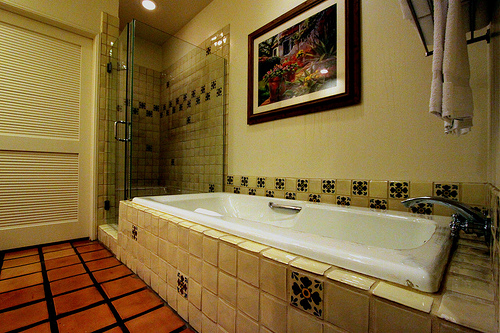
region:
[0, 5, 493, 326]
A bathroom in a house.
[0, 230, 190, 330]
Red tile on a floor.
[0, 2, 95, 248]
A white wooden door.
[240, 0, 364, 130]
Picture hanging on a wall.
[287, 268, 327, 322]
Decorative piece of tile.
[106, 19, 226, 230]
Glass shower door.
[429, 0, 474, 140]
Towels on a towel rack.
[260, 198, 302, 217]
Silver handle in a bathtub.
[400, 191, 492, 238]
Silver tub spout.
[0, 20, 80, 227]
Wooden slats on a door.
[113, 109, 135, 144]
Entrance to the glass door.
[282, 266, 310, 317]
Entrance to the glass door.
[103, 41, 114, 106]
Entrance to the glass door.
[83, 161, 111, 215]
Entrance to the glass door.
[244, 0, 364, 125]
a framed painting on wall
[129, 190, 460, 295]
a white porcelain bath tub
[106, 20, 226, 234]
a glass shower stall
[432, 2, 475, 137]
hanging tan towel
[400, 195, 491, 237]
chrome bath tub faucet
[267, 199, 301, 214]
chrome grab bar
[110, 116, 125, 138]
chrome shower door handle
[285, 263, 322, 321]
a decorative bathroom tile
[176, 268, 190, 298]
a decorative bathroom tile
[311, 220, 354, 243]
the sink is white in color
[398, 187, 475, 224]
this is a tap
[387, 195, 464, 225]
the tap is metallic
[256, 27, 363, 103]
this is a picture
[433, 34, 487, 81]
the towel is white in color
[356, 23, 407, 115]
this is the wall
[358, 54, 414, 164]
the wall is cream in color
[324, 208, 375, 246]
the sink is white in color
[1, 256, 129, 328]
this is the floor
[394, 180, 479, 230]
this is the tap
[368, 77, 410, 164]
this is the wall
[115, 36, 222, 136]
the glass is clear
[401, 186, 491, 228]
the tap is metallic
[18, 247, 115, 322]
the floor is tiled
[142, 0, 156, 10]
the light is on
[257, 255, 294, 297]
A tile in a wall.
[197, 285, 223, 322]
A tile in a wall.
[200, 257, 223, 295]
A tile in a wall.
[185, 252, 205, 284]
A tile in a wall.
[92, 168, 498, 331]
A white porcelain bathtub.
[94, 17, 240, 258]
A walk in shower with transparent glass door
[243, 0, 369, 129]
a painting with a brown frame